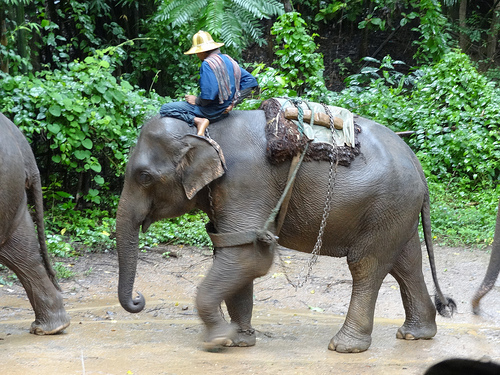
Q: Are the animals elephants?
A: Yes, all the animals are elephants.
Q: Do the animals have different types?
A: No, all the animals are elephants.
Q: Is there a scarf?
A: Yes, there is a scarf.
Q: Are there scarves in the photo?
A: Yes, there is a scarf.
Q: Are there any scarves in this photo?
A: Yes, there is a scarf.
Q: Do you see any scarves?
A: Yes, there is a scarf.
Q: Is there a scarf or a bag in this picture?
A: Yes, there is a scarf.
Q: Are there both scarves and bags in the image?
A: No, there is a scarf but no bags.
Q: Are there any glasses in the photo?
A: No, there are no glasses.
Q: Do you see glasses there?
A: No, there are no glasses.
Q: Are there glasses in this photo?
A: No, there are no glasses.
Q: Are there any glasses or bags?
A: No, there are no glasses or bags.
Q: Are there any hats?
A: Yes, there is a hat.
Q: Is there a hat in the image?
A: Yes, there is a hat.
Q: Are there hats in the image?
A: Yes, there is a hat.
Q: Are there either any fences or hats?
A: Yes, there is a hat.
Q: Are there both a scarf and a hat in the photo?
A: Yes, there are both a hat and a scarf.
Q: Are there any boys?
A: No, there are no boys.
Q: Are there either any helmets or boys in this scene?
A: No, there are no boys or helmets.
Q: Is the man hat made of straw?
A: Yes, the hat is made of straw.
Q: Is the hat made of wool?
A: No, the hat is made of straw.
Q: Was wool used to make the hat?
A: No, the hat is made of straw.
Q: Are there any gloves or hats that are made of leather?
A: No, there is a hat but it is made of straw.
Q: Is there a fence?
A: No, there are no fences.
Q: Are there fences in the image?
A: No, there are no fences.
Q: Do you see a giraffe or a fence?
A: No, there are no fences or giraffes.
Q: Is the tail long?
A: Yes, the tail is long.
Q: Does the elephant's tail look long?
A: Yes, the tail is long.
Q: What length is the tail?
A: The tail is long.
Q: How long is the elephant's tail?
A: The tail is long.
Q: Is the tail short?
A: No, the tail is long.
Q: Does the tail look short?
A: No, the tail is long.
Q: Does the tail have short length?
A: No, the tail is long.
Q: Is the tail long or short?
A: The tail is long.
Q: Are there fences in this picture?
A: No, there are no fences.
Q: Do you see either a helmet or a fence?
A: No, there are no fences or helmets.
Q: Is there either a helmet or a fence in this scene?
A: No, there are no fences or helmets.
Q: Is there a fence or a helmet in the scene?
A: No, there are no fences or helmets.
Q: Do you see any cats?
A: No, there are no cats.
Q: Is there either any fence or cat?
A: No, there are no cats or fences.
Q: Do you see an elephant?
A: Yes, there is an elephant.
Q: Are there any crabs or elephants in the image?
A: Yes, there is an elephant.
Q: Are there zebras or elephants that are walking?
A: Yes, the elephant is walking.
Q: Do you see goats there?
A: No, there are no goats.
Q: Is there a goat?
A: No, there are no goats.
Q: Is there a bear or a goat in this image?
A: No, there are no goats or bears.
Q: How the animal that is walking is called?
A: The animal is an elephant.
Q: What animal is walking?
A: The animal is an elephant.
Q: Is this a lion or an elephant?
A: This is an elephant.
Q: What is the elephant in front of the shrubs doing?
A: The elephant is walking.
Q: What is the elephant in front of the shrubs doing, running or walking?
A: The elephant is walking.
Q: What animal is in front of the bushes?
A: The elephant is in front of the bushes.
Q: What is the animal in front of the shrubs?
A: The animal is an elephant.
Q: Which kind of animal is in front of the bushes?
A: The animal is an elephant.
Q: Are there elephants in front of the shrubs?
A: Yes, there is an elephant in front of the shrubs.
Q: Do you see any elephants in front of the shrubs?
A: Yes, there is an elephant in front of the shrubs.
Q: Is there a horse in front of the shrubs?
A: No, there is an elephant in front of the shrubs.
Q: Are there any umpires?
A: No, there are no umpires.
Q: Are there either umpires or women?
A: No, there are no umpires or women.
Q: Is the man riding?
A: Yes, the man is riding.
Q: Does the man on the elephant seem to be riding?
A: Yes, the man is riding.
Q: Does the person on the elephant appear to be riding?
A: Yes, the man is riding.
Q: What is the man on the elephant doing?
A: The man is riding.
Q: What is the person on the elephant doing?
A: The man is riding.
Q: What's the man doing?
A: The man is riding.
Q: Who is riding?
A: The man is riding.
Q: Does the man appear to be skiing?
A: No, the man is riding.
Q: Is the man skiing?
A: No, the man is riding.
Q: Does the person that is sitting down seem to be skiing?
A: No, the man is riding.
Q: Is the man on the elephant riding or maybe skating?
A: The man is riding.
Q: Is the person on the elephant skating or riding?
A: The man is riding.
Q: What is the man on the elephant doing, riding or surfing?
A: The man is riding.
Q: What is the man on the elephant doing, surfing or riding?
A: The man is riding.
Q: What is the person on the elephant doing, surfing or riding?
A: The man is riding.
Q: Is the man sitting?
A: Yes, the man is sitting.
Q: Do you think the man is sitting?
A: Yes, the man is sitting.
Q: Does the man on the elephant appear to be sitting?
A: Yes, the man is sitting.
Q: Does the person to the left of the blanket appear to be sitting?
A: Yes, the man is sitting.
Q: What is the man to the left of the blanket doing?
A: The man is sitting.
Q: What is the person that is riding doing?
A: The man is sitting.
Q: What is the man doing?
A: The man is sitting.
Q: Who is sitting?
A: The man is sitting.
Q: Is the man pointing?
A: No, the man is sitting.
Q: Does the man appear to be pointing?
A: No, the man is sitting.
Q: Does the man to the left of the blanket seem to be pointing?
A: No, the man is sitting.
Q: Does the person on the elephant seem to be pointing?
A: No, the man is sitting.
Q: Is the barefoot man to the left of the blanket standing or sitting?
A: The man is sitting.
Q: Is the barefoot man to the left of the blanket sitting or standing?
A: The man is sitting.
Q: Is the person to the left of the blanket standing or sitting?
A: The man is sitting.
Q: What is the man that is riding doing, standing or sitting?
A: The man is sitting.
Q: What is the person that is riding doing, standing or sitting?
A: The man is sitting.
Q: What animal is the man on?
A: The man is on the elephant.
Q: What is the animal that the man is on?
A: The animal is an elephant.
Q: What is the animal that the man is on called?
A: The animal is an elephant.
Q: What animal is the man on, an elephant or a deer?
A: The man is on an elephant.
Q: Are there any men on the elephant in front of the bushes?
A: Yes, there is a man on the elephant.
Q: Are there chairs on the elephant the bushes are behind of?
A: No, there is a man on the elephant.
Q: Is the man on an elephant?
A: Yes, the man is on an elephant.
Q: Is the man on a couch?
A: No, the man is on an elephant.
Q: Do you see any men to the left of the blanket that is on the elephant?
A: Yes, there is a man to the left of the blanket.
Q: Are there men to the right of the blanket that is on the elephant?
A: No, the man is to the left of the blanket.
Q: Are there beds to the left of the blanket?
A: No, there is a man to the left of the blanket.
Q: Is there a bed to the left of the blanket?
A: No, there is a man to the left of the blanket.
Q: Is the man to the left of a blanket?
A: Yes, the man is to the left of a blanket.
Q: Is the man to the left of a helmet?
A: No, the man is to the left of a blanket.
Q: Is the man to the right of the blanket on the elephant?
A: No, the man is to the left of the blanket.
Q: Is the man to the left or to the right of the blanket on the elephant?
A: The man is to the left of the blanket.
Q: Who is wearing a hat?
A: The man is wearing a hat.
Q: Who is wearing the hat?
A: The man is wearing a hat.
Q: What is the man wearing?
A: The man is wearing a hat.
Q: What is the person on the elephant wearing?
A: The man is wearing a hat.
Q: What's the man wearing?
A: The man is wearing a hat.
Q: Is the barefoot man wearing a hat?
A: Yes, the man is wearing a hat.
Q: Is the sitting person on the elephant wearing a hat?
A: Yes, the man is wearing a hat.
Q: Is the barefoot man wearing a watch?
A: No, the man is wearing a hat.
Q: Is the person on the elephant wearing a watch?
A: No, the man is wearing a hat.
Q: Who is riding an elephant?
A: The man is riding an elephant.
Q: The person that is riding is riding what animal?
A: The man is riding an elephant.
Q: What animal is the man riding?
A: The man is riding an elephant.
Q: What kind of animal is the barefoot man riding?
A: The man is riding an elephant.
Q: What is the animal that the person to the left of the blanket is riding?
A: The animal is an elephant.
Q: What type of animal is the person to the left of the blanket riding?
A: The man is riding an elephant.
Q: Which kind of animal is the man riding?
A: The man is riding an elephant.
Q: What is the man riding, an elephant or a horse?
A: The man is riding an elephant.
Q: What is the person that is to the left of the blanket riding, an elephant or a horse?
A: The man is riding an elephant.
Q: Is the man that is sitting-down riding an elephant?
A: Yes, the man is riding an elephant.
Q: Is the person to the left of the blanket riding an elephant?
A: Yes, the man is riding an elephant.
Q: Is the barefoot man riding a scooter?
A: No, the man is riding an elephant.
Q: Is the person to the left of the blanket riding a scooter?
A: No, the man is riding an elephant.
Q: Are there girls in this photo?
A: No, there are no girls.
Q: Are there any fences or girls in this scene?
A: No, there are no girls or fences.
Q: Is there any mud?
A: Yes, there is mud.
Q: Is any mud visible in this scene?
A: Yes, there is mud.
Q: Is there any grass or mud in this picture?
A: Yes, there is mud.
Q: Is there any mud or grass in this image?
A: Yes, there is mud.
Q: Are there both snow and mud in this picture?
A: No, there is mud but no snow.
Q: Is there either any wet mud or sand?
A: Yes, there is wet mud.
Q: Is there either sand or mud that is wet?
A: Yes, the mud is wet.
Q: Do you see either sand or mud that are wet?
A: Yes, the mud is wet.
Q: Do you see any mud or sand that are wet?
A: Yes, the mud is wet.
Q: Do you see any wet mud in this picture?
A: Yes, there is wet mud.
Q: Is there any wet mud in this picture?
A: Yes, there is wet mud.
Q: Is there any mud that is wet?
A: Yes, there is mud that is wet.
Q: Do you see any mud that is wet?
A: Yes, there is mud that is wet.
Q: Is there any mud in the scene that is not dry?
A: Yes, there is wet mud.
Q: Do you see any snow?
A: No, there is no snow.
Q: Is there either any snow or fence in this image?
A: No, there are no snow or fences.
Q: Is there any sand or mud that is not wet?
A: No, there is mud but it is wet.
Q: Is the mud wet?
A: Yes, the mud is wet.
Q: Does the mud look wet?
A: Yes, the mud is wet.